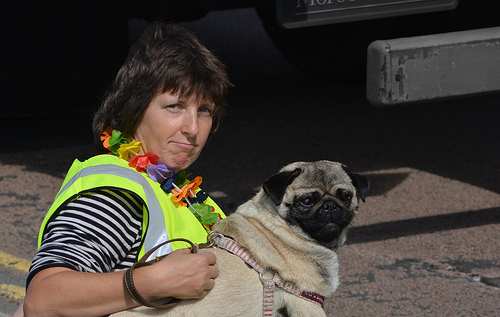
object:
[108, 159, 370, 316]
pug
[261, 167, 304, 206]
ear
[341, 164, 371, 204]
ear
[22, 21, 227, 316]
woman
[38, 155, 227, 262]
vest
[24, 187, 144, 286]
shirt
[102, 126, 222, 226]
necklace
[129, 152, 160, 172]
flower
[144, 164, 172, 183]
flower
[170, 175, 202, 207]
flower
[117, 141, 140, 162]
flower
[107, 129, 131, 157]
flower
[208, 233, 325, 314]
harness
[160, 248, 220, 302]
hand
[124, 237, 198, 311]
leash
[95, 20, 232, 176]
head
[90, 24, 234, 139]
hair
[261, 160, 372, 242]
head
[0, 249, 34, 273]
lines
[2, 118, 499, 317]
pavement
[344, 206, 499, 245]
shadows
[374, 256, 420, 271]
stain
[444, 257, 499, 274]
stain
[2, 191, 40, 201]
stain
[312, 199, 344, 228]
snout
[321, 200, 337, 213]
nose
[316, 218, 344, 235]
mouth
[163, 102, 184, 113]
eye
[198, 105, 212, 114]
eye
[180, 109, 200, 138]
nose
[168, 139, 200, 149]
mouth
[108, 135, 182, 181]
neck